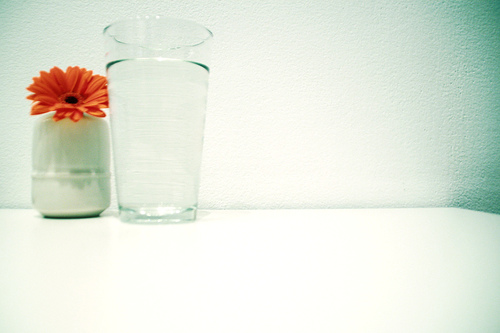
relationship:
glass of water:
[100, 14, 220, 224] [101, 55, 212, 208]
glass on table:
[100, 14, 220, 224] [10, 197, 455, 319]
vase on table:
[25, 120, 112, 220] [12, 210, 446, 316]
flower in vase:
[27, 65, 107, 119] [25, 120, 112, 220]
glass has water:
[100, 14, 220, 224] [122, 67, 191, 197]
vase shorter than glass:
[25, 120, 112, 220] [100, 14, 220, 224]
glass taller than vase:
[100, 14, 220, 224] [25, 114, 114, 223]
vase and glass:
[31, 120, 109, 220] [100, 14, 220, 224]